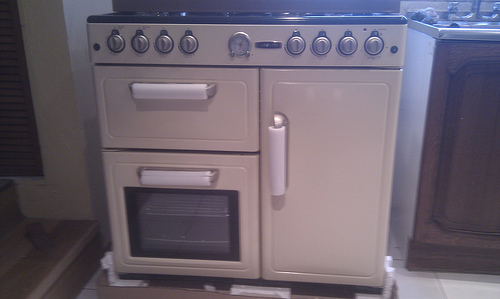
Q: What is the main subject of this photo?
A: Stove and oven.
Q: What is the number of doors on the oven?
A: 3.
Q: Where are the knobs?
A: On the stove.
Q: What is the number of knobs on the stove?
A: Nine.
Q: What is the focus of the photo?
A: The microwave.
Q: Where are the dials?
A: On the stove.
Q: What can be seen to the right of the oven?
A: Part of a cabinet.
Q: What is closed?
A: The oven door.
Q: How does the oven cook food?
A: Gas.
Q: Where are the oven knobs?
A: On the front of the stove.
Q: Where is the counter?
A: To the right of the stove.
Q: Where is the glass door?
A: On the bottom left side of the stove.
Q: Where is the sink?
A: To the right of the stove.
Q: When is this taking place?
A: Daytime.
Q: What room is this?
A: Kitchen.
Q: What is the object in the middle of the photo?
A: Stove.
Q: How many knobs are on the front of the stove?
A: Eight.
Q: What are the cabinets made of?
A: Wood.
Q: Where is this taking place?
A: In a kitchen.